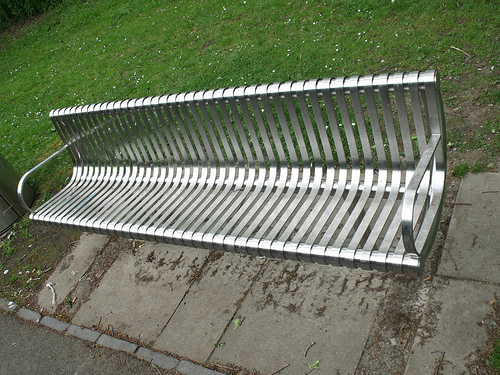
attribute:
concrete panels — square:
[69, 236, 213, 346]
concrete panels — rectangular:
[149, 247, 266, 363]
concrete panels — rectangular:
[206, 256, 396, 373]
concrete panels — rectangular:
[405, 276, 499, 373]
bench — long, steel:
[9, 45, 486, 305]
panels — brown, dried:
[31, 229, 101, 310]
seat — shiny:
[13, 63, 447, 278]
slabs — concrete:
[55, 182, 499, 367]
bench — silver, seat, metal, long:
[13, 67, 448, 278]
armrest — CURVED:
[397, 130, 439, 260]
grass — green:
[2, 4, 497, 165]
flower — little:
[378, 59, 386, 64]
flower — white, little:
[392, 31, 400, 38]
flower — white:
[311, 20, 317, 25]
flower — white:
[270, 67, 276, 74]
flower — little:
[195, 33, 200, 40]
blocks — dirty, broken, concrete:
[72, 253, 359, 374]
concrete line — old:
[41, 238, 117, 313]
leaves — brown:
[9, 227, 491, 374]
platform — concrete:
[63, 170, 495, 368]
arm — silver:
[399, 131, 447, 259]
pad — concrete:
[22, 152, 484, 372]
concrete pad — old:
[35, 169, 497, 369]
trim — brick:
[10, 291, 175, 357]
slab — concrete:
[27, 174, 490, 368]